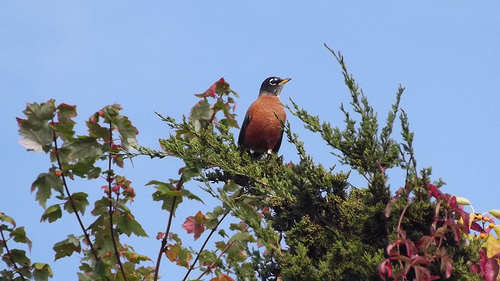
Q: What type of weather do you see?
A: It is clear.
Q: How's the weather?
A: It is clear.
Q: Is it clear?
A: Yes, it is clear.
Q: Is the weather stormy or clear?
A: It is clear.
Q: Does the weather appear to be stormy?
A: No, it is clear.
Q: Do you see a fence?
A: No, there are no fences.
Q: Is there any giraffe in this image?
A: No, there are no giraffes.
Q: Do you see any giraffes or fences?
A: No, there are no giraffes or fences.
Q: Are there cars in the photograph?
A: No, there are no cars.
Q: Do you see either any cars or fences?
A: No, there are no cars or fences.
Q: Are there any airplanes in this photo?
A: No, there are no airplanes.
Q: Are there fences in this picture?
A: No, there are no fences.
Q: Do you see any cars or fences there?
A: No, there are no fences or cars.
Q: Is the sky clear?
A: Yes, the sky is clear.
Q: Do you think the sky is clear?
A: Yes, the sky is clear.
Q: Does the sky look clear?
A: Yes, the sky is clear.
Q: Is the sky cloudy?
A: No, the sky is clear.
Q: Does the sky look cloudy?
A: No, the sky is clear.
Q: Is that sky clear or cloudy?
A: The sky is clear.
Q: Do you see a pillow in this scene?
A: No, there are no pillows.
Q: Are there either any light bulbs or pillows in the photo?
A: No, there are no pillows or light bulbs.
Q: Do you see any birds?
A: Yes, there is a bird.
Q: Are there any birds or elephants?
A: Yes, there is a bird.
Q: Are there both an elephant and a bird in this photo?
A: No, there is a bird but no elephants.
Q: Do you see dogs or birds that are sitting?
A: Yes, the bird is sitting.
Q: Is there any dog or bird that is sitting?
A: Yes, the bird is sitting.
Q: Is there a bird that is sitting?
A: Yes, there is a bird that is sitting.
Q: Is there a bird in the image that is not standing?
A: Yes, there is a bird that is sitting.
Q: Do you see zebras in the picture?
A: No, there are no zebras.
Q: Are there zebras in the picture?
A: No, there are no zebras.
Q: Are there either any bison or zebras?
A: No, there are no zebras or bison.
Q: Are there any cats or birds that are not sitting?
A: No, there is a bird but it is sitting.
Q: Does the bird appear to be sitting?
A: Yes, the bird is sitting.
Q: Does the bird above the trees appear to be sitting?
A: Yes, the bird is sitting.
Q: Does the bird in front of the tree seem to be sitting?
A: Yes, the bird is sitting.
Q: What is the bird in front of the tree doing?
A: The bird is sitting.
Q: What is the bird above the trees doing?
A: The bird is sitting.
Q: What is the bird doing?
A: The bird is sitting.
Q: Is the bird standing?
A: No, the bird is sitting.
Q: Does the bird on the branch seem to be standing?
A: No, the bird is sitting.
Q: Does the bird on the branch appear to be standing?
A: No, the bird is sitting.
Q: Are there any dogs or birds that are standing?
A: No, there is a bird but it is sitting.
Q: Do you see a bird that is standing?
A: No, there is a bird but it is sitting.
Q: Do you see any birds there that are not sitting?
A: No, there is a bird but it is sitting.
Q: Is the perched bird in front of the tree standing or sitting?
A: The bird is sitting.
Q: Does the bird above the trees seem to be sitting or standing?
A: The bird is sitting.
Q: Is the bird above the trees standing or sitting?
A: The bird is sitting.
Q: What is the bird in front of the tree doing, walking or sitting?
A: The bird is sitting.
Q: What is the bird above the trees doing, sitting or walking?
A: The bird is sitting.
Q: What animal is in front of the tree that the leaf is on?
A: The bird is in front of the tree.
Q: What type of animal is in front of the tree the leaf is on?
A: The animal is a bird.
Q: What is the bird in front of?
A: The bird is in front of the tree.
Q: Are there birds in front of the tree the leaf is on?
A: Yes, there is a bird in front of the tree.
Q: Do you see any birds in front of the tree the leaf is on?
A: Yes, there is a bird in front of the tree.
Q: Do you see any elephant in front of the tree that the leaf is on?
A: No, there is a bird in front of the tree.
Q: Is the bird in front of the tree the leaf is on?
A: Yes, the bird is in front of the tree.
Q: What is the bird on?
A: The bird is on the branch.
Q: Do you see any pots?
A: No, there are no pots.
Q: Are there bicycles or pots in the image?
A: No, there are no pots or bicycles.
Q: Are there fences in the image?
A: No, there are no fences.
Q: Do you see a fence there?
A: No, there are no fences.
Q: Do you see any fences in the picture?
A: No, there are no fences.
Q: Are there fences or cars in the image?
A: No, there are no fences or cars.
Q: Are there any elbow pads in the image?
A: No, there are no elbow pads.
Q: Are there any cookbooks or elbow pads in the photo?
A: No, there are no elbow pads or cookbooks.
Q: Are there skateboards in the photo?
A: No, there are no skateboards.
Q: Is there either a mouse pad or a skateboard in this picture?
A: No, there are no skateboards or mouse pads.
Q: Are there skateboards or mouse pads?
A: No, there are no skateboards or mouse pads.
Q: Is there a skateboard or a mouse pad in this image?
A: No, there are no skateboards or mouse pads.